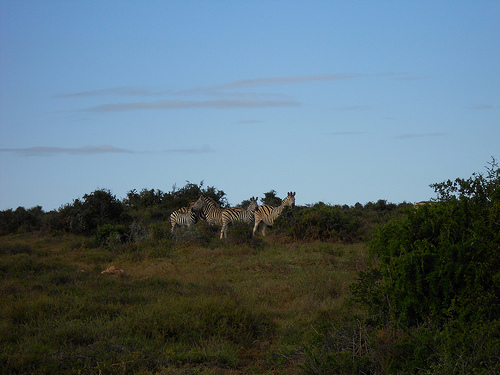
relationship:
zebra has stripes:
[251, 191, 296, 239] [255, 205, 281, 224]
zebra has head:
[251, 191, 296, 239] [286, 191, 296, 208]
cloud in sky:
[4, 143, 139, 160] [1, 2, 499, 208]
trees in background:
[0, 179, 389, 235] [10, 201, 488, 231]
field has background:
[17, 238, 469, 363] [10, 201, 488, 231]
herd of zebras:
[160, 176, 319, 246] [170, 190, 296, 242]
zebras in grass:
[170, 190, 296, 242] [163, 220, 326, 331]